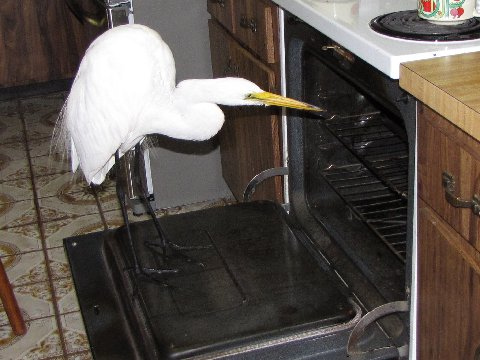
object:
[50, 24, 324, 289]
bird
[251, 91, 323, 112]
beak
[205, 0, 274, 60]
drawer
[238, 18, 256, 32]
handle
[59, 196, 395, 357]
oven door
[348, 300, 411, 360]
hinge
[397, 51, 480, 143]
countertop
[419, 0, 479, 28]
container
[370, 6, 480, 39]
burner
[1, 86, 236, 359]
floor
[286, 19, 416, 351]
oven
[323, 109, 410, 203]
rack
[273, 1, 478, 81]
top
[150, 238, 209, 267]
foot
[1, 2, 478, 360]
house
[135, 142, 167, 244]
leg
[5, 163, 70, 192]
pattern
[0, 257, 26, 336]
stool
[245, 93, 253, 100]
right eye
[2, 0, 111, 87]
paneling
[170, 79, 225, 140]
neck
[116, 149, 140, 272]
leg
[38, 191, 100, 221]
tile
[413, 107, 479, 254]
drawer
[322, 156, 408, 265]
rack